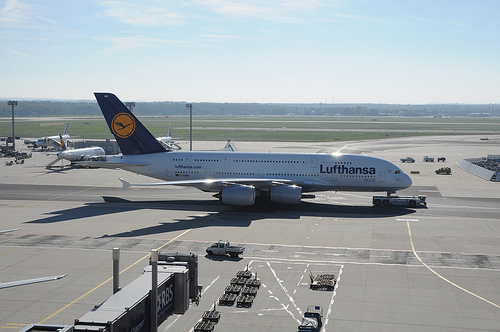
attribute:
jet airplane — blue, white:
[58, 90, 415, 222]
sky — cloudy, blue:
[2, 2, 495, 109]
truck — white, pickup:
[200, 237, 248, 264]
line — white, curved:
[398, 222, 498, 313]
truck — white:
[201, 237, 248, 259]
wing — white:
[0, 266, 70, 297]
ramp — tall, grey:
[148, 250, 204, 302]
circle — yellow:
[108, 114, 138, 138]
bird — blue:
[117, 121, 134, 130]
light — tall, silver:
[184, 100, 196, 149]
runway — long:
[229, 107, 457, 152]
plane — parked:
[62, 93, 409, 194]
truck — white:
[210, 236, 247, 257]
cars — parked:
[392, 144, 458, 180]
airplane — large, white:
[33, 79, 423, 223]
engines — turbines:
[215, 172, 305, 205]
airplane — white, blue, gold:
[64, 89, 430, 199]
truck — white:
[201, 234, 247, 252]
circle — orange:
[104, 110, 143, 137]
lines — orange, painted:
[68, 216, 228, 246]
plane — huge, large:
[84, 90, 421, 219]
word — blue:
[318, 161, 378, 176]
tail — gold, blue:
[91, 91, 167, 153]